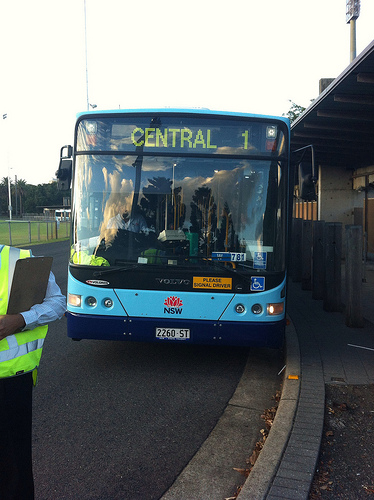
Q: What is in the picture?
A: A city bus.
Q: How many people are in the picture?
A: Two.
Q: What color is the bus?
A: Blue.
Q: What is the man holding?
A: A clipboard.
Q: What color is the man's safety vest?
A: Yellow.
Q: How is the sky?
A: It is white.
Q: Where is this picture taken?
A: At the bus station.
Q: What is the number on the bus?
A: 1.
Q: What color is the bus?
A: Blue.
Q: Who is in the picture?
A: A man in a yellow vest.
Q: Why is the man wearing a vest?
A: To direct traffic.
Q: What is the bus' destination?
A: Central.